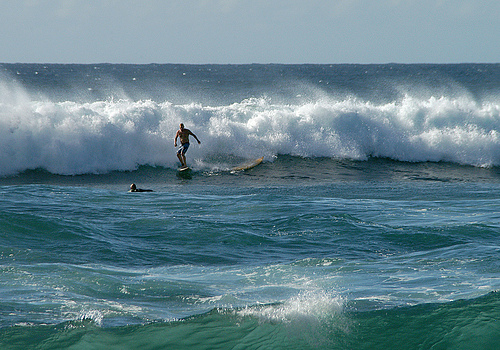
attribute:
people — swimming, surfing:
[125, 118, 205, 212]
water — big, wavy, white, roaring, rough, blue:
[4, 65, 493, 350]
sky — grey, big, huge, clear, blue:
[3, 3, 500, 77]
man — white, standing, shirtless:
[167, 122, 205, 166]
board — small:
[172, 163, 192, 176]